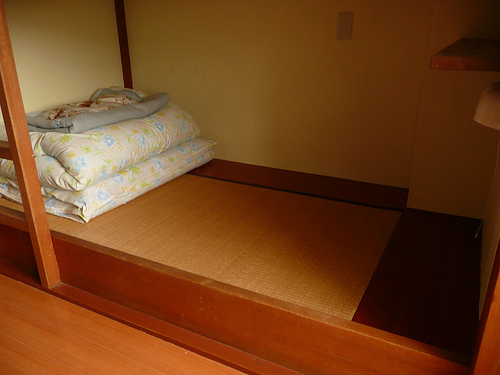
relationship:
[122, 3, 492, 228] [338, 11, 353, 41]
wall has a socket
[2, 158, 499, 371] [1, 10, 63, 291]
bed has a ladder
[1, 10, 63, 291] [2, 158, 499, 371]
ladder attached to bed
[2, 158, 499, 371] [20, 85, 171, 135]
bed has a blanket